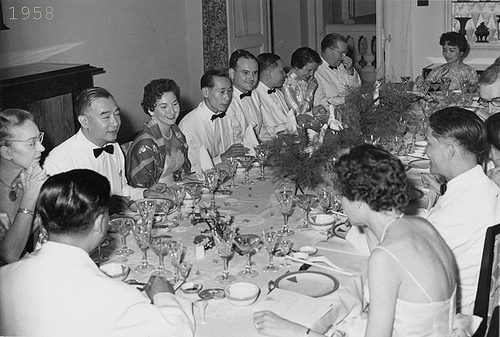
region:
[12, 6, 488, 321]
People are having food.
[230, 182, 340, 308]
Table cloth is white.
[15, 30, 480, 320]
Black and white picture.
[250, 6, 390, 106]
Door is open.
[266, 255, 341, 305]
Plate is white color.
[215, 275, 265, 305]
Bowl is white color.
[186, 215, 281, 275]
Wine glass are on table.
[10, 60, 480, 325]
Fifteen people are food.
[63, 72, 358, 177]
Men are wearing tie.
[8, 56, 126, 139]
Desk is behind the people.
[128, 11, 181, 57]
part of a wall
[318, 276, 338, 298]
edge of a plate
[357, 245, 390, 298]
part of a shoulder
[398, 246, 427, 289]
part of a back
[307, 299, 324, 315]
piece of a paper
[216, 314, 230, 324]
part of a table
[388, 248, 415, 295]
part of a string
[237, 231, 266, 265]
part of a glass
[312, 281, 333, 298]
edge of a dish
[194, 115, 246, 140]
man wearing white shirt and jacket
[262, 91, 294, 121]
man wearing white shirt and jacket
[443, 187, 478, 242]
man wearing white shirt and jacket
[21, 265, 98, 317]
man wearing white jacket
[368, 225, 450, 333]
woman wearing dress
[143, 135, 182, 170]
woman wearing dress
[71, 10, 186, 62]
wall in black and white photo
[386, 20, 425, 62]
wall in black and white photo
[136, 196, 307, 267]
decorated table in old photo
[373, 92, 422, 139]
decorated table in old photo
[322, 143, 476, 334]
a woman in a whit edress.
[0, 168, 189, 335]
a man in a white suit.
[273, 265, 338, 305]
a plate on top of a table.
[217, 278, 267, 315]
a bowl on top of a table.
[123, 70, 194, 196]
a woman having dinner.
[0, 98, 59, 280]
a woman resting her hand on her chin.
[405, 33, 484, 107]
a woman sitting at the head of a table.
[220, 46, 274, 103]
a man with a short haircut.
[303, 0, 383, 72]
a doorway.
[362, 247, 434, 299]
a strap of a dress.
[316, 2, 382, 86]
open doorway in background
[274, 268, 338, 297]
empty plate on table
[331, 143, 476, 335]
woman in front with white dress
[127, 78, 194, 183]
smiling woman with dark, curly hair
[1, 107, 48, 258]
woman with elbow on table wearing glasses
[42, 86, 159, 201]
smiling man second from left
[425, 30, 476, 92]
woman at end of the table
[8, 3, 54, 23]
date in upper corner, 1958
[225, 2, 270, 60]
white door in background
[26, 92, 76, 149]
wood paneled cupboard door